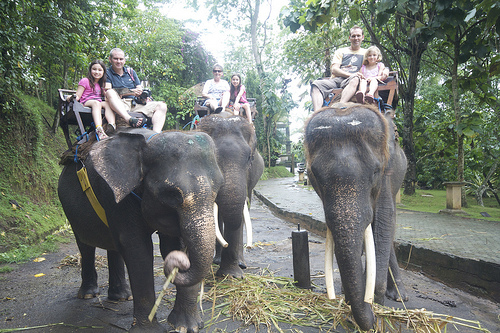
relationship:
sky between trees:
[144, 0, 312, 145] [9, 0, 484, 197]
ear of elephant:
[87, 129, 145, 204] [59, 118, 222, 332]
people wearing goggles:
[198, 62, 232, 114] [208, 68, 223, 75]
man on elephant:
[100, 47, 170, 133] [43, 130, 260, 310]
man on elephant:
[100, 47, 170, 133] [72, 147, 238, 324]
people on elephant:
[198, 62, 232, 114] [200, 114, 309, 255]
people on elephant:
[198, 62, 232, 114] [183, 106, 294, 234]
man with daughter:
[100, 47, 170, 133] [352, 39, 379, 105]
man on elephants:
[308, 24, 390, 111] [73, 107, 412, 319]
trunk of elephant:
[319, 186, 379, 328] [295, 100, 413, 329]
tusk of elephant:
[360, 225, 377, 303] [302, 103, 402, 331]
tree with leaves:
[197, 4, 287, 170] [212, 1, 262, 40]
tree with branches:
[197, 4, 287, 170] [261, 20, 268, 58]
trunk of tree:
[392, 56, 419, 198] [275, 2, 465, 185]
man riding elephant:
[308, 24, 390, 111] [296, 101, 416, 313]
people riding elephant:
[198, 59, 254, 119] [197, 111, 274, 293]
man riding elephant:
[100, 47, 170, 133] [59, 118, 222, 332]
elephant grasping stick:
[59, 118, 222, 332] [140, 265, 181, 322]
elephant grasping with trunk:
[59, 118, 222, 332] [163, 204, 222, 283]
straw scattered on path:
[219, 278, 433, 330] [38, 191, 484, 330]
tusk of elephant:
[322, 225, 338, 302] [306, 108, 409, 321]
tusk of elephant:
[360, 221, 376, 303] [306, 108, 409, 321]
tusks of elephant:
[213, 200, 255, 247] [198, 117, 270, 279]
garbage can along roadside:
[443, 181, 466, 213] [252, 166, 500, 263]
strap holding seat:
[75, 168, 107, 231] [59, 88, 148, 150]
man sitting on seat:
[100, 47, 170, 133] [54, 85, 124, 142]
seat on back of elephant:
[54, 85, 124, 142] [59, 118, 222, 332]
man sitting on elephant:
[308, 26, 365, 106] [305, 105, 426, 331]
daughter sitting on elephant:
[352, 39, 379, 105] [305, 105, 426, 331]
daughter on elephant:
[352, 39, 379, 105] [302, 103, 402, 331]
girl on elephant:
[231, 71, 254, 125] [197, 109, 263, 274]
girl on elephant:
[75, 58, 116, 140] [59, 118, 222, 332]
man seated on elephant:
[308, 24, 390, 111] [303, 104, 415, 327]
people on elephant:
[198, 62, 232, 114] [191, 110, 270, 284]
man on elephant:
[102, 43, 170, 133] [59, 118, 222, 332]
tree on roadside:
[354, 6, 482, 202] [297, 170, 483, 215]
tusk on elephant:
[360, 225, 377, 303] [303, 104, 415, 327]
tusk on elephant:
[322, 220, 339, 301] [303, 104, 415, 327]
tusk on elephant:
[242, 199, 255, 250] [187, 111, 267, 278]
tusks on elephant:
[213, 200, 255, 247] [187, 111, 267, 278]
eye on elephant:
[369, 163, 384, 185] [303, 104, 415, 327]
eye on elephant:
[164, 180, 181, 206] [59, 118, 222, 332]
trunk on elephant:
[322, 194, 376, 331] [302, 103, 402, 331]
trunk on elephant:
[209, 182, 249, 285] [187, 111, 267, 278]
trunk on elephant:
[162, 205, 219, 286] [59, 118, 222, 332]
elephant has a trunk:
[30, 82, 239, 330] [157, 190, 237, 330]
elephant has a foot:
[30, 103, 234, 329] [146, 262, 218, 330]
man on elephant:
[100, 47, 170, 133] [185, 122, 272, 293]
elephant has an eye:
[33, 99, 214, 317] [157, 169, 188, 210]